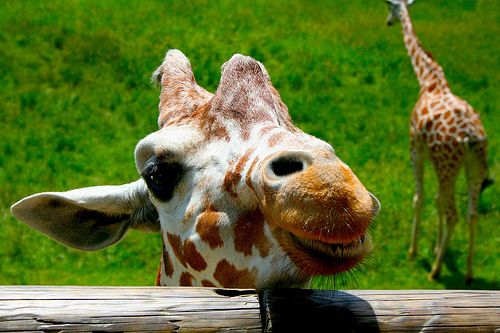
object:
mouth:
[270, 218, 379, 268]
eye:
[139, 156, 187, 203]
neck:
[396, 3, 449, 95]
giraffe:
[377, 0, 489, 289]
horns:
[146, 46, 219, 127]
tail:
[466, 136, 496, 217]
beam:
[0, 284, 498, 332]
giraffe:
[8, 49, 384, 290]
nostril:
[264, 147, 314, 183]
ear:
[8, 183, 140, 254]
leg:
[460, 163, 485, 278]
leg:
[429, 162, 461, 269]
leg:
[431, 189, 447, 243]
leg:
[404, 150, 425, 249]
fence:
[0, 285, 498, 333]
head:
[9, 48, 382, 290]